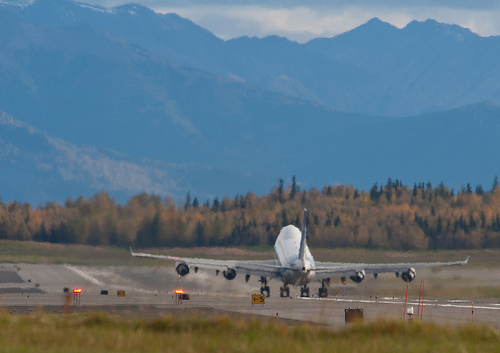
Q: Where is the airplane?
A: On the runway.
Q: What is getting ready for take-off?
A: The aeroplane.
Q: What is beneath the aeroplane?
A: The runway.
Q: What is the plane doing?
A: Taking off.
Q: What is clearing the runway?
A: The plane.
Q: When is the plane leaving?
A: On time.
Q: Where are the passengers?
A: In an airliner.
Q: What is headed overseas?
A: A plane.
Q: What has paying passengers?
A: A commercial jet.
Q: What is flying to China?
A: The jet.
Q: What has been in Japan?
A: The jet.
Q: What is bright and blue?
A: The sky.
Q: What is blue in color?
A: The sky.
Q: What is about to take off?
A: A jet.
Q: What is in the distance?
A: Trees.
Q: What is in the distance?
A: Tall mountains.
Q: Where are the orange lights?
A: On the runway.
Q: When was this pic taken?
A: During the day.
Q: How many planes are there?
A: 1.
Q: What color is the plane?
A: White.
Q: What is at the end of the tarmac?
A: Trees.